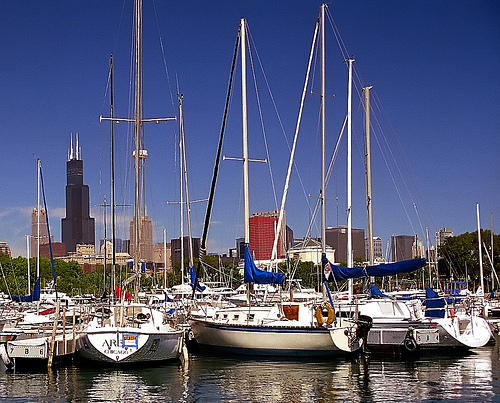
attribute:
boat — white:
[186, 279, 363, 362]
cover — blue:
[235, 248, 432, 277]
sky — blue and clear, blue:
[1, 0, 498, 267]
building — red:
[40, 79, 127, 287]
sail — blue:
[321, 255, 431, 277]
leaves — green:
[4, 253, 105, 303]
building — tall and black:
[48, 147, 117, 257]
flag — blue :
[235, 240, 292, 297]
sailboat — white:
[189, 301, 371, 360]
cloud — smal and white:
[0, 207, 160, 229]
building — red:
[247, 207, 281, 260]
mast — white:
[202, 72, 331, 348]